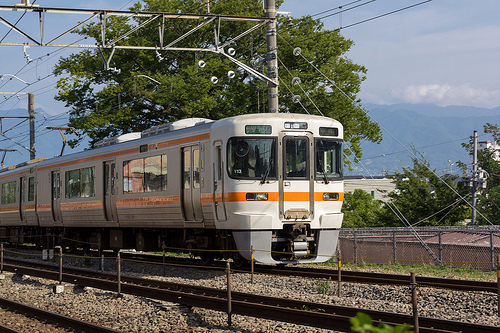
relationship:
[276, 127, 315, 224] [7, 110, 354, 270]
door on train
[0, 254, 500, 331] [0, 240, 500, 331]
gravel along train tracks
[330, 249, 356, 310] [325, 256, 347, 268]
post with stripe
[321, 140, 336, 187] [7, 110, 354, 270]
wiper in train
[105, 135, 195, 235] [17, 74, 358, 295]
window on train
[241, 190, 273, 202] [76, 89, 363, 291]
headlight on train